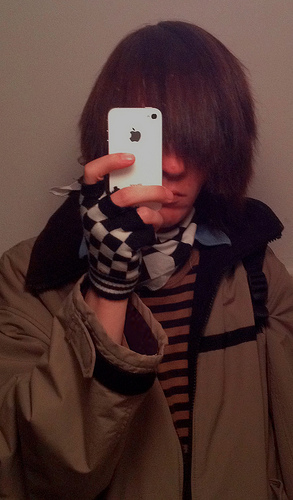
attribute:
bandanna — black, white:
[49, 173, 196, 290]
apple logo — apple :
[128, 126, 143, 143]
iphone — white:
[91, 100, 173, 213]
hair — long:
[77, 28, 264, 217]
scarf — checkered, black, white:
[91, 189, 205, 291]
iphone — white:
[103, 102, 174, 197]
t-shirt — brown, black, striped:
[131, 262, 200, 480]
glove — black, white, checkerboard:
[77, 185, 160, 299]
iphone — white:
[107, 106, 161, 191]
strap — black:
[236, 238, 274, 330]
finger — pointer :
[78, 146, 134, 188]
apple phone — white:
[103, 104, 162, 199]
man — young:
[5, 23, 285, 432]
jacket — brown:
[12, 275, 287, 489]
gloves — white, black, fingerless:
[58, 179, 154, 299]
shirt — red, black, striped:
[126, 272, 202, 468]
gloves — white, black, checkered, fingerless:
[61, 185, 166, 260]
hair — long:
[79, 16, 258, 221]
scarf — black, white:
[141, 231, 195, 294]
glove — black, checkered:
[79, 189, 154, 303]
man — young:
[0, 102, 287, 497]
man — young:
[10, 33, 282, 475]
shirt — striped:
[133, 245, 208, 433]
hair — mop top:
[74, 40, 256, 208]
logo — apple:
[124, 124, 143, 145]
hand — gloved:
[71, 165, 180, 332]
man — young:
[43, 10, 275, 326]